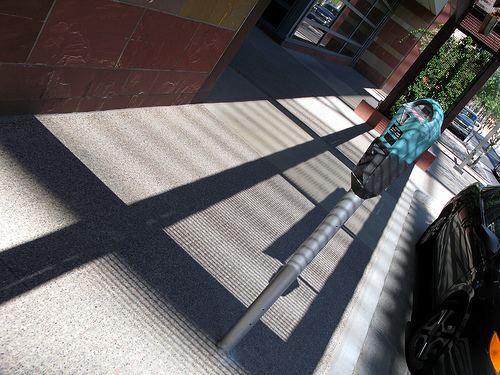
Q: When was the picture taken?
A: In the daytime.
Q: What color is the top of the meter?
A: Blue.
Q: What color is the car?
A: Black.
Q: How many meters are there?
A: 1.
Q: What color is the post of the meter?
A: Gray.